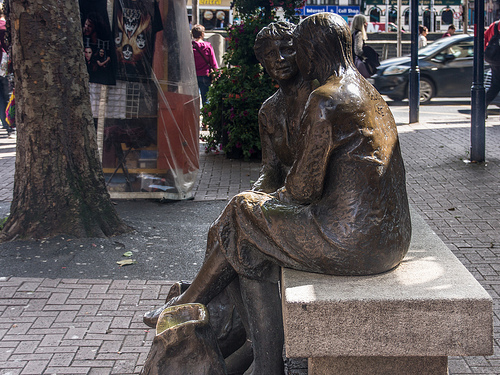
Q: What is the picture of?
A: A sculpture.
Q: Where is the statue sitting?
A: On a bench.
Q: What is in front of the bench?
A: Tree trunk.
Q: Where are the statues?
A: On the bench.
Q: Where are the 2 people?
A: Sitting on bench.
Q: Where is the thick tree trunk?
A: On the left.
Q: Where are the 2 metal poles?
A: On the right.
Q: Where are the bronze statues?
A: On the bench.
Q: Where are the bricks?
A: On the ground.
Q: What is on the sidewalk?
A: Statues.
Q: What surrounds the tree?
A: Dirt.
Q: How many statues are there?
A: Two.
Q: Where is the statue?
A: On the bench.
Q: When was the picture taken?
A: In the daytime.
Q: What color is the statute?
A: Gray brown.